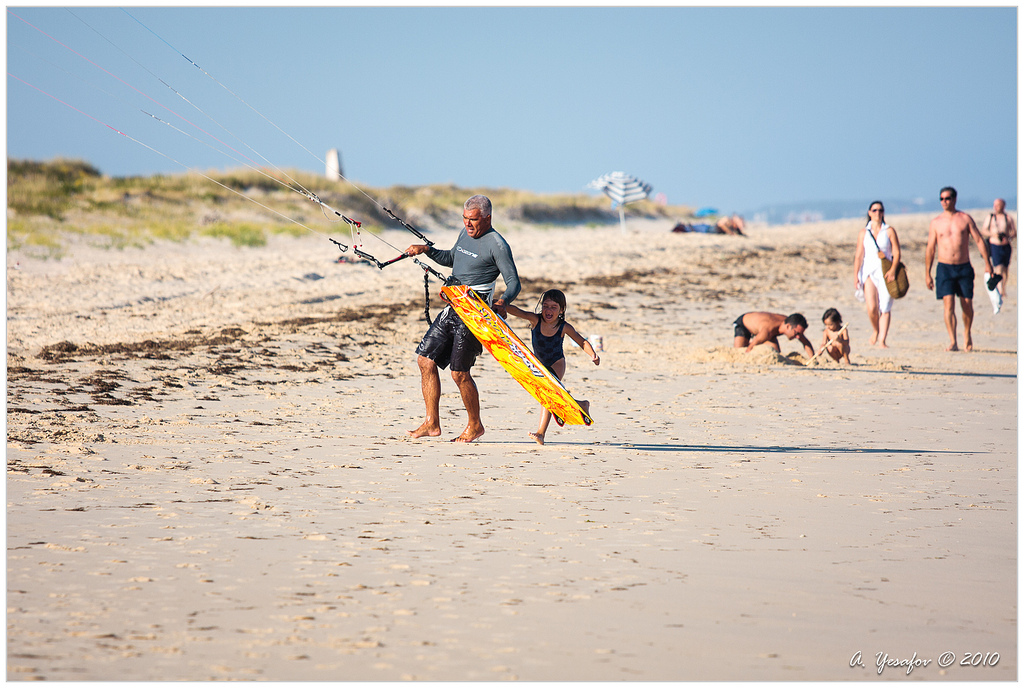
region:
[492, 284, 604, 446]
Little girl wearing black swimsuit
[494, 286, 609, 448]
Little girl in black swimsuit running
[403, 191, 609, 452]
Older man with little girl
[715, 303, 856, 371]
Man and little girl playing in the sand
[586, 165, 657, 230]
Blue and white beach umbrella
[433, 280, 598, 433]
Yellow and orange surfboard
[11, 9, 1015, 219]
Clear blue sky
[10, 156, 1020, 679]
People in the sand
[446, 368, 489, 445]
leg of person on beach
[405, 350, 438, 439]
leg of person on beach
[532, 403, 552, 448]
leg of person on beach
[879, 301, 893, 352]
leg of person on beach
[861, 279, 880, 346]
leg of person on beach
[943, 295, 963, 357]
leg of person on beach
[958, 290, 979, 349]
leg of person on beach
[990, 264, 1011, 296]
leg of person on beach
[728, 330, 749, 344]
leg of person on beach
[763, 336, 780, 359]
leg of person on beach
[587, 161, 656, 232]
beach umbrella in the sand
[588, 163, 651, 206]
beach umbrella is blue and white striped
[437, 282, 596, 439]
boogie board is yellow and orange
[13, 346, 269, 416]
seaweed on the sand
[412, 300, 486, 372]
man is wearing a bathing suit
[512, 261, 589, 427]
A person is standing up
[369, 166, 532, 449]
A person is standing up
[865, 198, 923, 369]
A person is standing up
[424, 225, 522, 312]
the man is wearing a sports shirt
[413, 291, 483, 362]
the man is wearing shorts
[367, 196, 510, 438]
the man is holding a metal bar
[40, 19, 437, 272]
cables are attached to the bar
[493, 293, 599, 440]
the man is holding a child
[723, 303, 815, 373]
a man is playing on the sand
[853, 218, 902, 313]
the woman is wearing a white dress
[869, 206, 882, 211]
the woman is wearing sunglasses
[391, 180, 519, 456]
a person on the beach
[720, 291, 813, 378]
a person on the beach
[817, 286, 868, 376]
a person on the beach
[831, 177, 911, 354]
a person on the beach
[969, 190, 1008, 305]
a person on the beach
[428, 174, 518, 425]
a person on the beach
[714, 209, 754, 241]
a person on the beach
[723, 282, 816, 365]
a person on the beach